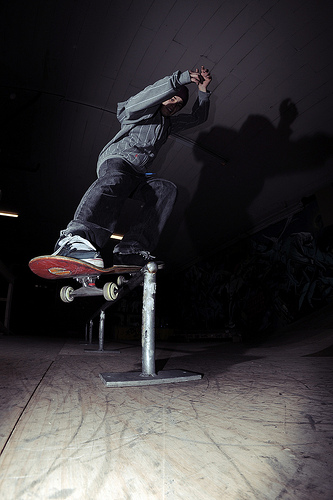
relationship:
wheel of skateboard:
[91, 271, 124, 312] [16, 211, 172, 324]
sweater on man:
[79, 67, 241, 220] [31, 31, 260, 289]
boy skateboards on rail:
[49, 65, 213, 269] [97, 259, 158, 376]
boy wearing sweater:
[49, 65, 213, 269] [94, 67, 215, 177]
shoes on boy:
[33, 227, 160, 281] [49, 65, 213, 269]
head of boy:
[153, 77, 194, 121] [49, 65, 213, 269]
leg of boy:
[112, 171, 181, 255] [49, 65, 213, 269]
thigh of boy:
[141, 176, 171, 194] [49, 65, 213, 269]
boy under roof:
[49, 65, 213, 269] [0, 0, 331, 266]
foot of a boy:
[49, 235, 105, 267] [49, 65, 213, 269]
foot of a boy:
[105, 245, 163, 271] [49, 65, 213, 269]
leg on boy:
[61, 154, 136, 245] [49, 65, 213, 269]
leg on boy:
[104, 171, 179, 255] [49, 65, 213, 269]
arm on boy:
[121, 67, 179, 116] [49, 65, 213, 269]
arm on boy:
[170, 95, 209, 132] [49, 65, 213, 269]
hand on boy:
[187, 63, 222, 92] [49, 65, 213, 269]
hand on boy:
[195, 63, 214, 95] [49, 65, 213, 269]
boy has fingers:
[49, 65, 213, 269] [200, 65, 213, 79]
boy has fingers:
[49, 65, 213, 269] [190, 69, 203, 84]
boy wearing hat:
[46, 59, 215, 271] [173, 84, 187, 102]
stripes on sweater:
[94, 67, 212, 172] [94, 67, 215, 177]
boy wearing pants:
[46, 59, 215, 271] [56, 157, 183, 243]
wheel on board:
[101, 279, 119, 302] [28, 254, 151, 303]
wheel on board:
[59, 284, 75, 302] [28, 254, 151, 303]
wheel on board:
[115, 273, 128, 286] [28, 254, 151, 303]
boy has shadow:
[49, 65, 213, 269] [190, 98, 332, 283]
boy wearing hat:
[49, 65, 213, 269] [173, 84, 190, 107]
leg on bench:
[145, 264, 162, 379] [91, 260, 201, 387]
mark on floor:
[187, 400, 260, 498] [2, 323, 330, 498]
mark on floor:
[212, 409, 329, 428] [2, 323, 330, 498]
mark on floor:
[41, 377, 91, 498] [2, 323, 330, 498]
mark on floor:
[112, 401, 142, 498] [2, 323, 330, 498]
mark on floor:
[0, 371, 63, 415] [2, 323, 330, 498]